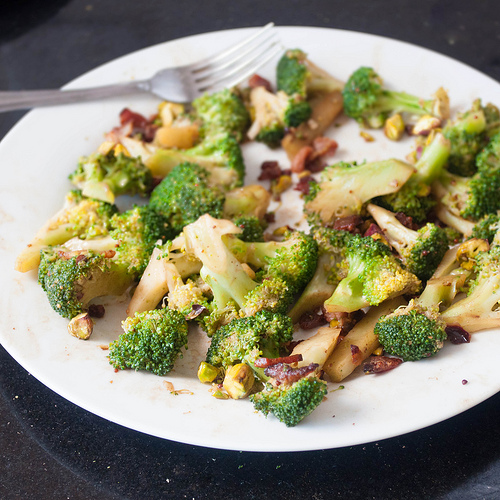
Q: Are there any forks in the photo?
A: Yes, there is a fork.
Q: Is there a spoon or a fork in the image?
A: Yes, there is a fork.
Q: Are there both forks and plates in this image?
A: Yes, there are both a fork and a plate.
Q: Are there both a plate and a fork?
A: Yes, there are both a fork and a plate.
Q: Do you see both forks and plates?
A: Yes, there are both a fork and a plate.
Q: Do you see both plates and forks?
A: Yes, there are both a fork and a plate.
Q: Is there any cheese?
A: No, there is no cheese.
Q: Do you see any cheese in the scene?
A: No, there is no cheese.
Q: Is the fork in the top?
A: Yes, the fork is in the top of the image.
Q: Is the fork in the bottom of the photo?
A: No, the fork is in the top of the image.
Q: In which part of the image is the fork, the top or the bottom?
A: The fork is in the top of the image.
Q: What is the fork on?
A: The fork is on the plate.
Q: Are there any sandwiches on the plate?
A: No, there is a fork on the plate.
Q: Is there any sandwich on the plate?
A: No, there is a fork on the plate.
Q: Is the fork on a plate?
A: Yes, the fork is on a plate.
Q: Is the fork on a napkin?
A: No, the fork is on a plate.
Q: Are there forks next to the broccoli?
A: Yes, there is a fork next to the broccoli.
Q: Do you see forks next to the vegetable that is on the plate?
A: Yes, there is a fork next to the broccoli.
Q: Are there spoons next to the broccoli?
A: No, there is a fork next to the broccoli.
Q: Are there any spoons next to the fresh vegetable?
A: No, there is a fork next to the broccoli.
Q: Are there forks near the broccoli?
A: Yes, there is a fork near the broccoli.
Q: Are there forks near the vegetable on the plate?
A: Yes, there is a fork near the broccoli.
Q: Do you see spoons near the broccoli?
A: No, there is a fork near the broccoli.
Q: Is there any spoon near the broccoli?
A: No, there is a fork near the broccoli.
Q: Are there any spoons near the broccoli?
A: No, there is a fork near the broccoli.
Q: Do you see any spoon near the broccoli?
A: No, there is a fork near the broccoli.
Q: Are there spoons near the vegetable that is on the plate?
A: No, there is a fork near the broccoli.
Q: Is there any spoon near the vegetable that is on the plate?
A: No, there is a fork near the broccoli.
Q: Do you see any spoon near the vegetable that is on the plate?
A: No, there is a fork near the broccoli.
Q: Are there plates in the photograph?
A: Yes, there is a plate.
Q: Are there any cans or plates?
A: Yes, there is a plate.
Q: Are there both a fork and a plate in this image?
A: Yes, there are both a plate and a fork.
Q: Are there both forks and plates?
A: Yes, there are both a plate and a fork.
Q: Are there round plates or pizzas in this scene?
A: Yes, there is a round plate.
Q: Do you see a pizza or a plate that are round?
A: Yes, the plate is round.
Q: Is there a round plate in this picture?
A: Yes, there is a round plate.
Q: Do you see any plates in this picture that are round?
A: Yes, there is a plate that is round.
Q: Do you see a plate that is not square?
A: Yes, there is a round plate.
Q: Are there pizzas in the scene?
A: No, there are no pizzas.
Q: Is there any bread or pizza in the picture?
A: No, there are no pizzas or breads.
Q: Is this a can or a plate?
A: This is a plate.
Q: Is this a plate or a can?
A: This is a plate.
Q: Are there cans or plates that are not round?
A: No, there is a plate but it is round.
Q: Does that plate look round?
A: Yes, the plate is round.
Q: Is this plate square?
A: No, the plate is round.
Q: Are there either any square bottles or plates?
A: No, there is a plate but it is round.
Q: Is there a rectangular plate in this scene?
A: No, there is a plate but it is round.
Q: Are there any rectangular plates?
A: No, there is a plate but it is round.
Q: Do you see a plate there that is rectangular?
A: No, there is a plate but it is round.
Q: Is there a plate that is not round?
A: No, there is a plate but it is round.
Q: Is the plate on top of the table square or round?
A: The plate is round.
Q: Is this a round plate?
A: Yes, this is a round plate.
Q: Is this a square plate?
A: No, this is a round plate.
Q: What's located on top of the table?
A: The plate is on top of the table.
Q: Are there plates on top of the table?
A: Yes, there is a plate on top of the table.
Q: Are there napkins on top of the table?
A: No, there is a plate on top of the table.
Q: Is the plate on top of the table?
A: Yes, the plate is on top of the table.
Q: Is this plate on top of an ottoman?
A: No, the plate is on top of the table.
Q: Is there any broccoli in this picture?
A: Yes, there is broccoli.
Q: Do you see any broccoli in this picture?
A: Yes, there is broccoli.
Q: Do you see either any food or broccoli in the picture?
A: Yes, there is broccoli.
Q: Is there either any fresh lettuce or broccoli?
A: Yes, there is fresh broccoli.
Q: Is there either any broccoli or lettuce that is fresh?
A: Yes, the broccoli is fresh.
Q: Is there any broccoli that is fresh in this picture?
A: Yes, there is fresh broccoli.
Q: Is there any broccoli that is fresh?
A: Yes, there is broccoli that is fresh.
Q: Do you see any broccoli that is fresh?
A: Yes, there is broccoli that is fresh.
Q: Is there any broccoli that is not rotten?
A: Yes, there is fresh broccoli.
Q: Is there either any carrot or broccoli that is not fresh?
A: No, there is broccoli but it is fresh.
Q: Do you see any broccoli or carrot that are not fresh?
A: No, there is broccoli but it is fresh.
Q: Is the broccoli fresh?
A: Yes, the broccoli is fresh.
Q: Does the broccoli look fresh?
A: Yes, the broccoli is fresh.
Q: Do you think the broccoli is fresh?
A: Yes, the broccoli is fresh.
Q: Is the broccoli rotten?
A: No, the broccoli is fresh.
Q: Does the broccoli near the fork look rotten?
A: No, the broccoli is fresh.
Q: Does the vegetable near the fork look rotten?
A: No, the broccoli is fresh.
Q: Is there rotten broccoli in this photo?
A: No, there is broccoli but it is fresh.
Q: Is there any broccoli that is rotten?
A: No, there is broccoli but it is fresh.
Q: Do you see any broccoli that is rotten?
A: No, there is broccoli but it is fresh.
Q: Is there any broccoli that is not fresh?
A: No, there is broccoli but it is fresh.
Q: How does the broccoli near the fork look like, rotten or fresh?
A: The broccoli is fresh.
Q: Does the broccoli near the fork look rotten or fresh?
A: The broccoli is fresh.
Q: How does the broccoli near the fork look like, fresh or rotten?
A: The broccoli is fresh.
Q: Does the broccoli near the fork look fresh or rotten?
A: The broccoli is fresh.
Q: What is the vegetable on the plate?
A: The vegetable is broccoli.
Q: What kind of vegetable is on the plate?
A: The vegetable is broccoli.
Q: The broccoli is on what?
A: The broccoli is on the plate.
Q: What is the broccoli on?
A: The broccoli is on the plate.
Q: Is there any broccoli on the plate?
A: Yes, there is broccoli on the plate.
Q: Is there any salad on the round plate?
A: No, there is broccoli on the plate.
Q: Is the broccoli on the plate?
A: Yes, the broccoli is on the plate.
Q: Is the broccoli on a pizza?
A: No, the broccoli is on the plate.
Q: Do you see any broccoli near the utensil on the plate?
A: Yes, there is broccoli near the fork.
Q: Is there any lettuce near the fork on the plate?
A: No, there is broccoli near the fork.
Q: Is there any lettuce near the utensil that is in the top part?
A: No, there is broccoli near the fork.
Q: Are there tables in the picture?
A: Yes, there is a table.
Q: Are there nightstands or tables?
A: Yes, there is a table.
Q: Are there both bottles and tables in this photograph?
A: No, there is a table but no bottles.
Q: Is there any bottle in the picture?
A: No, there are no bottles.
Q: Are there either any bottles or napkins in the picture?
A: No, there are no bottles or napkins.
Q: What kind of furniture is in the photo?
A: The furniture is a table.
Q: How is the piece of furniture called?
A: The piece of furniture is a table.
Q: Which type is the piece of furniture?
A: The piece of furniture is a table.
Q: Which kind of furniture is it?
A: The piece of furniture is a table.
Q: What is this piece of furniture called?
A: This is a table.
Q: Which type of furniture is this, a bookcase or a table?
A: This is a table.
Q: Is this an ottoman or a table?
A: This is a table.